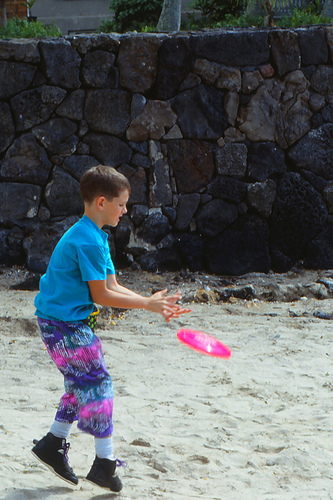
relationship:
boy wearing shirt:
[28, 153, 192, 495] [32, 215, 115, 319]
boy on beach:
[28, 153, 192, 495] [9, 279, 331, 483]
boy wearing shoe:
[28, 153, 192, 495] [29, 430, 79, 485]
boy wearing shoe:
[28, 153, 192, 495] [84, 457, 124, 491]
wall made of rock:
[184, 23, 301, 242] [216, 140, 245, 179]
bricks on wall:
[122, 82, 226, 141] [1, 43, 331, 162]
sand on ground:
[0, 289, 332, 499] [0, 270, 332, 498]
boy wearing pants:
[28, 153, 192, 495] [41, 324, 105, 434]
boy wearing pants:
[28, 153, 192, 495] [42, 309, 113, 438]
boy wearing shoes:
[28, 153, 192, 495] [31, 430, 129, 494]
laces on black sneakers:
[62, 439, 72, 459] [29, 431, 122, 493]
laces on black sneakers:
[113, 458, 122, 467] [29, 431, 122, 493]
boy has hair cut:
[75, 153, 166, 251] [59, 155, 135, 205]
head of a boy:
[71, 165, 133, 228] [28, 153, 192, 495]